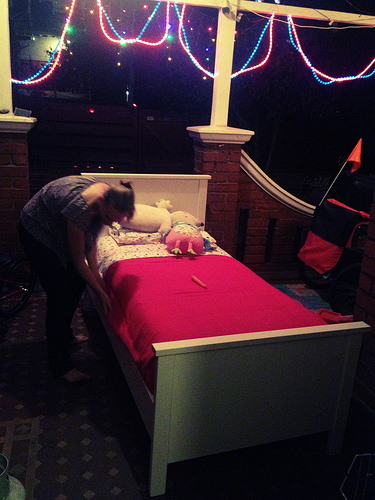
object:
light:
[63, 26, 73, 36]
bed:
[82, 173, 375, 496]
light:
[65, 29, 71, 36]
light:
[293, 36, 374, 87]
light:
[176, 25, 204, 66]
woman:
[17, 169, 136, 375]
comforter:
[90, 255, 336, 373]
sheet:
[101, 232, 166, 257]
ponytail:
[169, 208, 201, 224]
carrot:
[192, 275, 210, 290]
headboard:
[79, 172, 209, 232]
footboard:
[150, 322, 372, 467]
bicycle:
[4, 256, 30, 320]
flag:
[347, 138, 361, 173]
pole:
[321, 162, 346, 200]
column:
[200, 142, 242, 252]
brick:
[218, 185, 239, 195]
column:
[2, 134, 31, 262]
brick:
[5, 166, 28, 179]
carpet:
[8, 300, 118, 493]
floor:
[1, 266, 374, 495]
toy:
[162, 212, 209, 255]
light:
[261, 27, 274, 64]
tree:
[247, 28, 315, 168]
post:
[211, 12, 233, 129]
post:
[0, 5, 13, 111]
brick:
[205, 152, 228, 162]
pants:
[20, 237, 77, 370]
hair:
[109, 184, 136, 221]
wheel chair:
[298, 202, 368, 307]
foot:
[65, 370, 83, 382]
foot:
[74, 334, 90, 346]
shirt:
[25, 173, 85, 241]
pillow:
[111, 227, 165, 247]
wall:
[241, 188, 303, 278]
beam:
[236, 0, 373, 20]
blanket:
[301, 201, 356, 276]